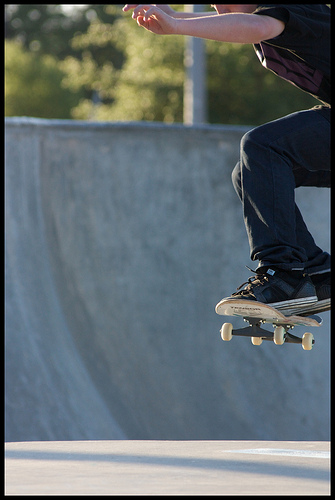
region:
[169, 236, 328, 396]
feet on skateboard jumping in the air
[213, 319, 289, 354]
white wheels on the bottom of skateboard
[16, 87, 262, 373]
large sloped cement ramp for skateboarding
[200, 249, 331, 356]
black leather skate shoes on feet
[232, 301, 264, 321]
black logo on bottom of wood skateboard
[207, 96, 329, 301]
jeans being worn by the skateboarder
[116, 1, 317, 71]
skateboarder has arm in the air for balance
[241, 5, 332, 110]
black tee shirt with logo on front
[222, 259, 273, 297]
black laces on skateboarder's shoe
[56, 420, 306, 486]
shadow on pavement from skateboarder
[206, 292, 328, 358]
a skateboard color black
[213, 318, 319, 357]
skateboard has white wheels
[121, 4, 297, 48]
left arm of skater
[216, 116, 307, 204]
knees are bend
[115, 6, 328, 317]
skater is crouched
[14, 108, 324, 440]
a blue fence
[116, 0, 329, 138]
boy wears a black top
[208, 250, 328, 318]
black shoes with white soles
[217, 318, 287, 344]
front wheels of skateboard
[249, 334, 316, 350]
back wheels of skateboard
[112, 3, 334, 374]
he jumped with his skateboard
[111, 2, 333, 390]
he is doing an ollie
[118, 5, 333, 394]
he is doing a skateboard trick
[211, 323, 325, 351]
the wheels of the skateboard are white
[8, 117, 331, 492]
this is an empty pool for skating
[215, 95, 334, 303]
he is wearing dark pants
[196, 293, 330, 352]
the bottom of the skateboard is white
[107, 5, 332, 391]
he is about to land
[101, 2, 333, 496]
he holds his arms out for balance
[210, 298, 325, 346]
a skate board in the air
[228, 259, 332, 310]
a pair of black tennis shoes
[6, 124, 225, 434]
a concrete wall ramp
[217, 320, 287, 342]
front wheels of a skate board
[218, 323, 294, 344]
white front wheels of a skate board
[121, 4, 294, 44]
a persons left arm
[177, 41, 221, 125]
a gray metal pole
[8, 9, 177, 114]
trees behind the wall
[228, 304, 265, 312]
writing on the skate board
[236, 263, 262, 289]
shoe strings on shoe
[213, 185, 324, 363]
person doing a trick on a skate board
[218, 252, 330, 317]
person wearing black sneakers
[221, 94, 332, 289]
person wearing blue jeans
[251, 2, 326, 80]
person wearing a black tee shirt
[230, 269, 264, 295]
shoe laces in a sneaker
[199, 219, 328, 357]
skate board in the sky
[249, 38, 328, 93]
logo on a tee shirt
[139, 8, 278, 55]
person with there arms out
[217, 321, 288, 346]
white wheels on a skateboard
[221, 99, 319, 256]
person wearing blue jeans